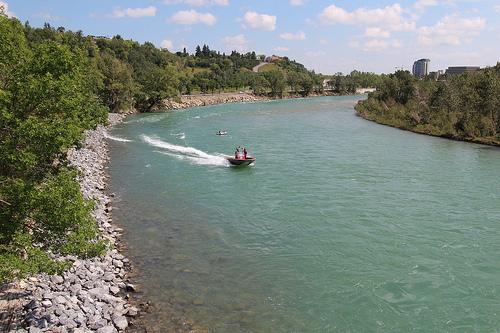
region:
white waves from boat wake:
[142, 136, 228, 168]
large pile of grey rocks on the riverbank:
[18, 270, 140, 331]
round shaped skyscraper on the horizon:
[409, 59, 430, 81]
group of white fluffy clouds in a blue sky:
[315, 2, 422, 44]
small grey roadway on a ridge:
[248, 56, 269, 73]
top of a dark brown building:
[449, 64, 481, 74]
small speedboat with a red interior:
[223, 154, 255, 169]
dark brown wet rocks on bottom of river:
[136, 208, 272, 331]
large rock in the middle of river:
[216, 127, 229, 137]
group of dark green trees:
[192, 68, 284, 95]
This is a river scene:
[0, 0, 498, 330]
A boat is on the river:
[224, 145, 256, 167]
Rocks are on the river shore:
[0, 111, 134, 331]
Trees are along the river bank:
[0, 2, 182, 279]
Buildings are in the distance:
[410, 56, 484, 77]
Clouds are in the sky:
[99, 0, 497, 54]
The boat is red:
[227, 145, 258, 168]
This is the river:
[111, 94, 498, 331]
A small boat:
[214, 127, 229, 137]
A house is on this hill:
[251, 52, 283, 67]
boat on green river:
[223, 135, 252, 175]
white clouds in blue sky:
[91, 5, 140, 36]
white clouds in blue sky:
[132, 10, 174, 42]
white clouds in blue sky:
[181, 20, 223, 50]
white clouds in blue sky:
[211, 0, 254, 40]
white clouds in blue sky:
[274, 15, 323, 51]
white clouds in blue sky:
[356, 11, 399, 63]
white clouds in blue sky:
[386, 17, 446, 64]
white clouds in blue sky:
[431, 7, 471, 47]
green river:
[238, 182, 331, 249]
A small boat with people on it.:
[227, 145, 256, 167]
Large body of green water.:
[115, 91, 499, 331]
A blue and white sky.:
[1, 1, 498, 67]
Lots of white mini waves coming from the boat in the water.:
[141, 133, 232, 168]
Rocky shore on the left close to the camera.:
[13, 251, 131, 331]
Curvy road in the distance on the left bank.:
[252, 59, 267, 71]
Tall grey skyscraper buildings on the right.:
[413, 55, 433, 77]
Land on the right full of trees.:
[356, 67, 499, 147]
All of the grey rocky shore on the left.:
[0, 108, 135, 331]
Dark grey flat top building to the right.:
[446, 65, 482, 72]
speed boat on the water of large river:
[224, 148, 256, 167]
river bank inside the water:
[108, 108, 202, 329]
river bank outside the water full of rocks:
[7, 110, 124, 328]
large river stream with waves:
[110, 106, 494, 329]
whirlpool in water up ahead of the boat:
[362, 275, 424, 310]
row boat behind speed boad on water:
[215, 130, 227, 135]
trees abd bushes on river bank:
[353, 69, 498, 146]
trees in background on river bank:
[129, 70, 351, 89]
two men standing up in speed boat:
[231, 146, 251, 159]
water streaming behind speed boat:
[104, 118, 227, 168]